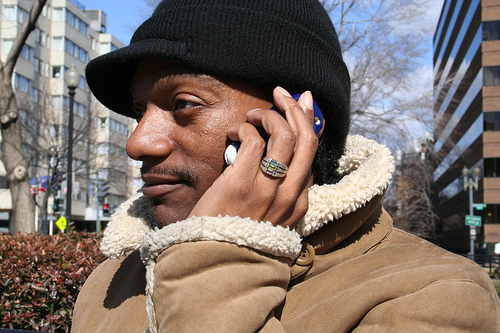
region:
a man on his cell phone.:
[54, 7, 475, 317]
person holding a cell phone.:
[67, 1, 446, 278]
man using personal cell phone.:
[42, 12, 445, 309]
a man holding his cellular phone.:
[32, 11, 437, 306]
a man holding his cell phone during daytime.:
[45, 13, 452, 311]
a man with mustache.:
[67, 26, 260, 221]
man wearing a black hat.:
[44, 4, 386, 181]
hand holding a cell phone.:
[217, 83, 333, 214]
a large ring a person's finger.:
[252, 145, 294, 190]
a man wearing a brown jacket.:
[19, 20, 483, 326]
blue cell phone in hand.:
[239, 98, 334, 161]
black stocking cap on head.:
[142, 9, 329, 60]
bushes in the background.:
[20, 245, 77, 297]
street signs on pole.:
[459, 170, 484, 245]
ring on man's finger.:
[260, 150, 292, 177]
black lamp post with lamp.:
[62, 70, 79, 197]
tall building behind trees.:
[51, 15, 88, 57]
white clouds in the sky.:
[392, 69, 431, 122]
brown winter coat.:
[324, 250, 428, 311]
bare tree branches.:
[368, 11, 412, 126]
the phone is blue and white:
[234, 102, 369, 194]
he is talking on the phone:
[214, 113, 342, 188]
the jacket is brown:
[101, 261, 481, 328]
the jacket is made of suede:
[121, 258, 498, 326]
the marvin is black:
[93, 18, 370, 103]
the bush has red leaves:
[2, 239, 84, 318]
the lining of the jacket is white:
[138, 218, 298, 263]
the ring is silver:
[260, 106, 291, 188]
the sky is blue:
[367, 13, 439, 139]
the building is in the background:
[11, 5, 105, 227]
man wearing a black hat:
[81, 0, 348, 156]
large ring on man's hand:
[253, 145, 299, 195]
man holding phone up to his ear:
[200, 68, 325, 211]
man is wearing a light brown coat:
[75, 127, 490, 327]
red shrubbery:
[0, 226, 135, 326]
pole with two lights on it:
[455, 160, 490, 266]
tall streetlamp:
[45, 55, 80, 260]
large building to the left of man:
[0, 0, 170, 250]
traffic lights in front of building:
[35, 165, 115, 240]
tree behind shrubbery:
[0, 0, 61, 301]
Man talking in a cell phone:
[50, 2, 495, 330]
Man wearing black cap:
[42, 2, 496, 331]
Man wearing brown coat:
[51, 0, 495, 331]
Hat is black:
[74, 0, 372, 98]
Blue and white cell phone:
[219, 84, 335, 192]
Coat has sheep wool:
[54, 216, 497, 331]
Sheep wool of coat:
[147, 219, 302, 241]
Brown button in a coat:
[285, 228, 330, 274]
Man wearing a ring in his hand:
[60, 0, 400, 332]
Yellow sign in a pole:
[50, 211, 77, 240]